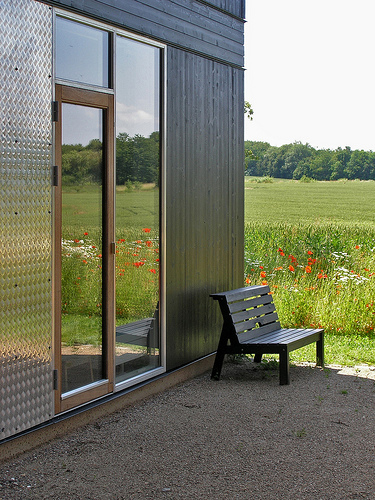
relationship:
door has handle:
[54, 86, 114, 415] [108, 241, 117, 256]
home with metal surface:
[4, 0, 246, 464] [2, 3, 55, 442]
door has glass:
[54, 86, 114, 415] [63, 104, 108, 395]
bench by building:
[210, 282, 328, 378] [1, 1, 245, 419]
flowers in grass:
[251, 243, 357, 304] [245, 227, 374, 366]